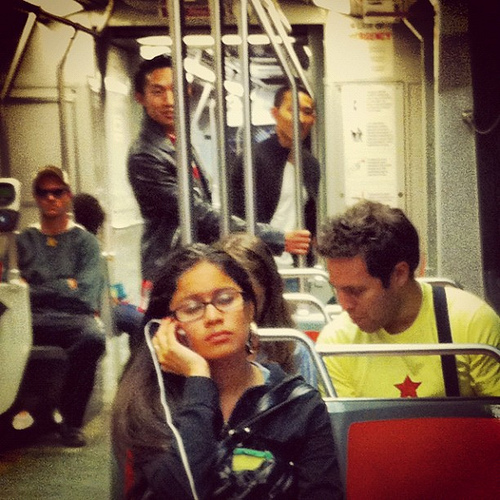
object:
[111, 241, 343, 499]
woman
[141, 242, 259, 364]
head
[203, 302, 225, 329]
nose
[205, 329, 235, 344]
mouth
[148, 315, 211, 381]
hand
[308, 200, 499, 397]
man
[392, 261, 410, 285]
ear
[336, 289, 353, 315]
nose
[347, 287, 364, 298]
eye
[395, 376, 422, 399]
star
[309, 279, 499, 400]
shirt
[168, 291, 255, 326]
glasses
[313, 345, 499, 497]
seat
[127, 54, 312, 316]
man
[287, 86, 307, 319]
pole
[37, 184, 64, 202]
sunglasses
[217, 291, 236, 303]
eyes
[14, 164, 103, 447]
man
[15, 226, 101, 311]
arms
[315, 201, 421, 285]
hair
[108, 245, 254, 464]
hair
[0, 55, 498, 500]
people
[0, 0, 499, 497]
train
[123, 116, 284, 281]
jacket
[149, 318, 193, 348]
device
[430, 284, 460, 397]
strap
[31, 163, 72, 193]
hat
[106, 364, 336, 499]
jacket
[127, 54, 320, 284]
men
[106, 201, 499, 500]
people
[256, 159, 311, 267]
shirt